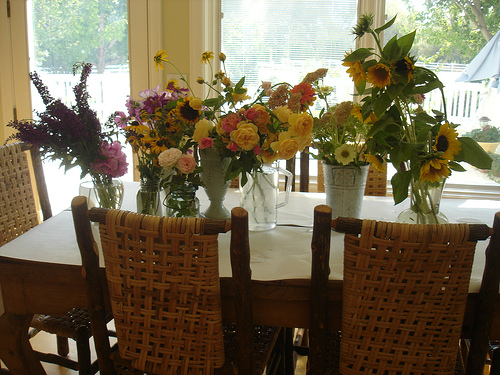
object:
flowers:
[153, 48, 168, 71]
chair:
[70, 195, 302, 374]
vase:
[198, 147, 233, 219]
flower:
[158, 148, 183, 170]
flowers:
[315, 85, 335, 93]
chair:
[310, 203, 500, 373]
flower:
[364, 63, 392, 89]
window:
[22, 0, 133, 221]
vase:
[321, 156, 371, 234]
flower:
[333, 143, 358, 166]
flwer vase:
[239, 158, 294, 232]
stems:
[97, 177, 107, 209]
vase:
[166, 186, 200, 218]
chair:
[0, 141, 52, 249]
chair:
[301, 145, 387, 197]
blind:
[217, 0, 359, 110]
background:
[0, 0, 499, 189]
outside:
[219, 0, 357, 110]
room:
[0, 0, 499, 375]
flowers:
[341, 47, 368, 87]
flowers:
[349, 11, 371, 39]